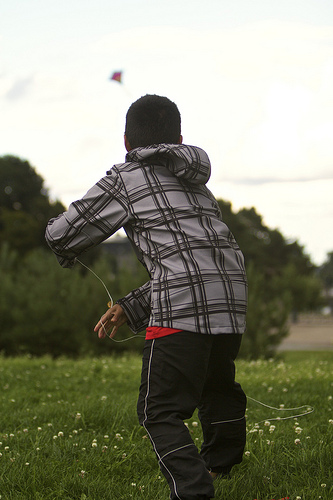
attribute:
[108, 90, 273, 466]
boy — playing, flying, dark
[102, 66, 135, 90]
kite — red, far, flying, blurry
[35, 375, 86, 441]
grass — green, covered, dark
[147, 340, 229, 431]
pants — black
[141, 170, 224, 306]
jacket — grey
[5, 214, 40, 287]
trees — far, green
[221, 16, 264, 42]
sky — cloud